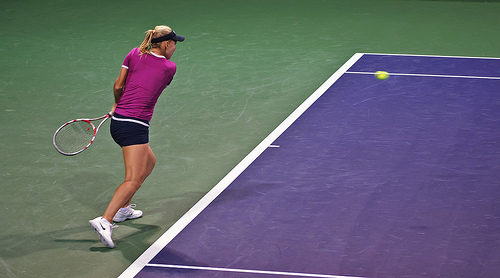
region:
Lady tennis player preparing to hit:
[87, 23, 185, 248]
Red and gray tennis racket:
[51, 110, 108, 155]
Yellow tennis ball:
[372, 68, 391, 88]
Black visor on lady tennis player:
[151, 29, 184, 49]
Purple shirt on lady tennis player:
[113, 47, 179, 122]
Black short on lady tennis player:
[108, 116, 151, 148]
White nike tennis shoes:
[89, 200, 142, 250]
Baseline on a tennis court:
[116, 47, 368, 275]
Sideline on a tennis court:
[145, 262, 350, 277]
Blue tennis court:
[133, 51, 497, 276]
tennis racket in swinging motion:
[51, 98, 123, 158]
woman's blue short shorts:
[106, 110, 157, 154]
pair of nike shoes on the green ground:
[87, 198, 147, 249]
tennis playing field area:
[141, 36, 498, 276]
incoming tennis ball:
[370, 64, 394, 84]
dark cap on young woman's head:
[142, 22, 196, 47]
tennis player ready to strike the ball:
[70, 17, 185, 247]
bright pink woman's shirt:
[108, 45, 174, 130]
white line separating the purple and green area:
[92, 37, 405, 274]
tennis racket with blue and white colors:
[48, 94, 121, 161]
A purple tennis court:
[208, 80, 490, 275]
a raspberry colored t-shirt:
[103, 48, 205, 118]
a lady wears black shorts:
[100, 106, 172, 206]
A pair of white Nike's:
[53, 191, 170, 253]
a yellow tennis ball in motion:
[368, 37, 398, 90]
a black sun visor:
[151, 14, 199, 57]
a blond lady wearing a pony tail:
[118, 13, 212, 72]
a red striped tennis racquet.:
[28, 67, 122, 170]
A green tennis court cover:
[191, 7, 367, 110]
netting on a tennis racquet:
[53, 121, 95, 151]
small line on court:
[244, 128, 326, 160]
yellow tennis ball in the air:
[373, 64, 458, 96]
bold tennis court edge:
[250, 90, 339, 124]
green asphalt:
[225, 19, 315, 79]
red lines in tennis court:
[49, 104, 106, 137]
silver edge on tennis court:
[33, 115, 74, 178]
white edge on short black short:
[108, 103, 165, 133]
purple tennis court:
[265, 32, 469, 207]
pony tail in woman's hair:
[123, 10, 163, 50]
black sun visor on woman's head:
[158, 21, 198, 54]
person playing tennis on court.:
[51, 10, 482, 268]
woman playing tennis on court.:
[2, 5, 447, 255]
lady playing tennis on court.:
[0, 1, 435, 246]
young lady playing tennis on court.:
[25, 0, 447, 265]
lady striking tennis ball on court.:
[26, 7, 446, 257]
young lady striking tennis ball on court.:
[56, 0, 446, 255]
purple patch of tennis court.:
[300, 126, 465, 256]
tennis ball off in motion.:
[355, 55, 410, 110]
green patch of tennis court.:
[195, 10, 305, 71]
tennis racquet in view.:
[41, 96, 98, 158]